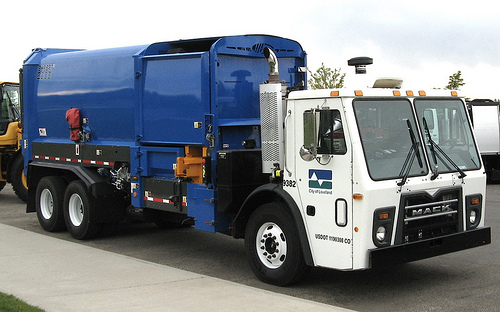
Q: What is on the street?
A: A truck.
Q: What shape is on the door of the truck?
A: Triangles.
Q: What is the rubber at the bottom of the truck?
A: The tires.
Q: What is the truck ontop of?
A: The street.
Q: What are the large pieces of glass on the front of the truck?
A: Windows.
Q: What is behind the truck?
A: A tractor.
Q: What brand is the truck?
A: A Mack truck.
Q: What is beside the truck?
A: A sidewalk.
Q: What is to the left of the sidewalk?
A: Grass.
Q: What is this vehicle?
A: Truck.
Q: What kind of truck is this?
A: Dump truck.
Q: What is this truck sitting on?
A: Pavement.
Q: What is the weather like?
A: Clear.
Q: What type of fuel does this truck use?
A: Diesel.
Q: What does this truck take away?
A: Trash.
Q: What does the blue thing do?
A: Compress trash.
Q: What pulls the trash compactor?
A: Engine.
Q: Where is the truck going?
A: Nowhere.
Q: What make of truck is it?
A: Mack truck.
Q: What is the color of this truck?
A: Blue and White.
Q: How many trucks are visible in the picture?
A: One.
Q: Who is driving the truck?
A: Truck driver.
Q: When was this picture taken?
A: Daytime.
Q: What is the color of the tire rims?
A: White.